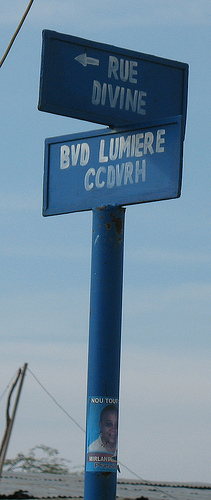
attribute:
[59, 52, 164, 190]
writing — white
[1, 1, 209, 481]
sky — clear 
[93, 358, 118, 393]
pole — blue 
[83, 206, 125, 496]
blue pole — thick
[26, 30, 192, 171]
sign — blue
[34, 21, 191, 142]
sign — blue 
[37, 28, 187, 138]
top sign — blue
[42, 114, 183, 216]
bottom sign — blue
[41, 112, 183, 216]
sign — blue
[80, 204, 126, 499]
pole — blue 